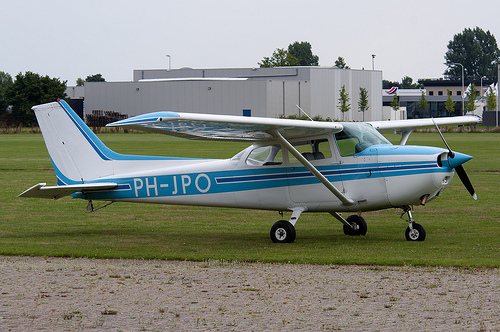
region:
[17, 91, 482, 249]
propeller fixed at the nose of plane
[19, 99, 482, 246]
the plane has three wheels for running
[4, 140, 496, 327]
green color grass next to brown color dirt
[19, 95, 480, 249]
colors in the plane are white and blue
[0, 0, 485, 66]
the sky is clear and grayish white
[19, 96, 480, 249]
the plane is sitting on top of grass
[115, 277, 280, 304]
gravel track on the side of plane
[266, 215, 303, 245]
black wheel on the plane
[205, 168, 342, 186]
blue stripe on side of plane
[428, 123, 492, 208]
black propellers on front of plane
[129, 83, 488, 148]
long wing on the plane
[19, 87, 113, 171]
tail of the plane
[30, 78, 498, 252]
small plane on the ground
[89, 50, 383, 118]
building in the background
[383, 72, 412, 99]
small flag flying on the pole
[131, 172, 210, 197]
PH-JPO on the side of a plane.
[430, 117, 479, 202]
Two blade black and white propeller on the front of a plane.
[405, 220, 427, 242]
Front black wheel.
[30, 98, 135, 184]
Blue and white tail end of a plane.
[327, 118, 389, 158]
Front windshield of a plane.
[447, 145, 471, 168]
Blue nose of a plane.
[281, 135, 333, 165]
Large rectangle side window of a plane.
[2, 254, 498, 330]
Tan dirt area.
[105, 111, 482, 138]
Single blue and white top wing on a plane.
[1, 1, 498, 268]
A small aircraft parked at an airfield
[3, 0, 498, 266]
A blue and white plane parked in front of a hangar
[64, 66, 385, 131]
An airplane hangar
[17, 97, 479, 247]
A small white airplane with blue trim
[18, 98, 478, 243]
A small plane with the call letters PH-JPO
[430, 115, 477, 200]
The propeller of a small aircraft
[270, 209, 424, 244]
The wheels of a small aircraft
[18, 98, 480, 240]
A blue and white small airplane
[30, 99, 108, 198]
Teh tail fin of a blue and white airplane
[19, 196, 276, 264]
The grass is green.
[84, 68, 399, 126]
A white building behind the plane.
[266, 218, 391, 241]
The wheels of the plane.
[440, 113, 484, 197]
The propeller in front of the plane.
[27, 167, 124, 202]
The right wing of the plane.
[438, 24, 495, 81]
A tree behind the building.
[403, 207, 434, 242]
The landing gear in front of the plane.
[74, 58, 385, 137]
The building is white.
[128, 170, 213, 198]
The white letters on the plane.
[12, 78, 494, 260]
a blue and white airplane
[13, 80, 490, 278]
a blue and white airplane on the ground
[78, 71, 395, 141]
a white concrete building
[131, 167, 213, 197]
white letters on a airplane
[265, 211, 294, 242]
a wheel on a airplane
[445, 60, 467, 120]
a tall metal security light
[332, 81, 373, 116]
two small trees near a building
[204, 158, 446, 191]
a blue stripe on a airplane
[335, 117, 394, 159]
a windshield on a airplane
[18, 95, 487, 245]
The plane parked in the grass field.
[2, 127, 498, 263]
The field of grass.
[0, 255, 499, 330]
The dirt next to the grass field.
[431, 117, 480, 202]
The black propeller on the plane.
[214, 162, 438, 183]
The small stripe on the plane.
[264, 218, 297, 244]
the wheel on the plane.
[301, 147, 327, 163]
The seats in the cockpit.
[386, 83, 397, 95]
The flag waving in the wind.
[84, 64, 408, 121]
The white building behind the plane.